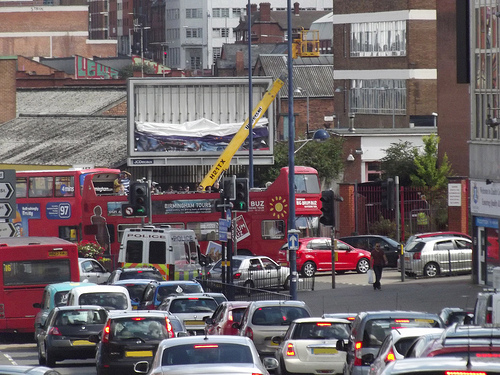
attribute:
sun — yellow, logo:
[268, 196, 291, 219]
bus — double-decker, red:
[223, 164, 322, 264]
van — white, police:
[113, 223, 207, 283]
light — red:
[102, 325, 112, 338]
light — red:
[161, 317, 172, 336]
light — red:
[130, 315, 146, 322]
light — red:
[282, 341, 295, 355]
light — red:
[313, 320, 332, 327]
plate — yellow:
[309, 346, 339, 355]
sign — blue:
[215, 216, 231, 245]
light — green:
[133, 202, 146, 217]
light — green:
[234, 200, 248, 212]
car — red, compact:
[279, 237, 373, 276]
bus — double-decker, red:
[3, 164, 124, 259]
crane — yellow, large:
[195, 25, 321, 189]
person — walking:
[367, 242, 392, 295]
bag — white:
[368, 265, 379, 284]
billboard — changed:
[126, 75, 278, 168]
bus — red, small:
[4, 234, 81, 342]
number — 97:
[58, 201, 71, 217]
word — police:
[122, 233, 169, 242]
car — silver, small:
[209, 254, 304, 292]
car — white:
[278, 315, 351, 373]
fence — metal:
[341, 181, 471, 240]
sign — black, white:
[446, 180, 463, 209]